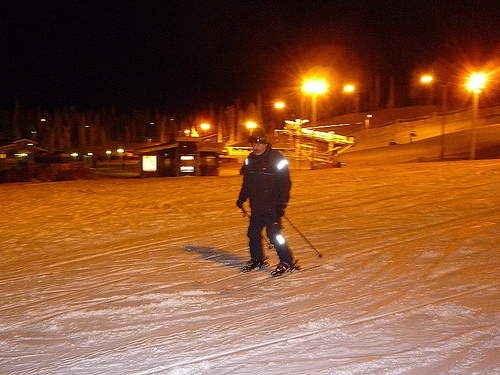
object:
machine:
[273, 118, 355, 169]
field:
[0, 157, 500, 374]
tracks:
[0, 220, 247, 282]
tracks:
[323, 175, 497, 235]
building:
[132, 136, 224, 176]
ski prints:
[0, 229, 500, 373]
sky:
[4, 0, 490, 130]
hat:
[247, 126, 269, 144]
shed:
[127, 136, 221, 186]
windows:
[140, 154, 159, 172]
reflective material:
[244, 158, 248, 166]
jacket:
[238, 143, 292, 205]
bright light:
[276, 235, 286, 244]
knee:
[270, 238, 278, 243]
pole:
[468, 96, 479, 159]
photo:
[2, 2, 499, 370]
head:
[248, 126, 269, 156]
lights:
[301, 76, 331, 98]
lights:
[201, 124, 211, 130]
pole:
[310, 96, 318, 124]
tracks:
[288, 178, 397, 210]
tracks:
[135, 282, 496, 373]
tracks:
[359, 224, 495, 310]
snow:
[0, 159, 500, 374]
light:
[462, 70, 490, 94]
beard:
[255, 148, 266, 156]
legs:
[265, 213, 295, 262]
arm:
[240, 166, 250, 202]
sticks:
[239, 204, 272, 250]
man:
[236, 126, 299, 277]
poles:
[282, 212, 325, 260]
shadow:
[177, 243, 273, 273]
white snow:
[171, 343, 239, 375]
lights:
[246, 121, 258, 130]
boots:
[271, 260, 300, 277]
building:
[0, 138, 50, 159]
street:
[62, 107, 500, 170]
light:
[421, 74, 432, 83]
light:
[343, 83, 354, 93]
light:
[275, 102, 285, 109]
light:
[276, 158, 289, 170]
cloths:
[237, 142, 292, 262]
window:
[13, 153, 30, 157]